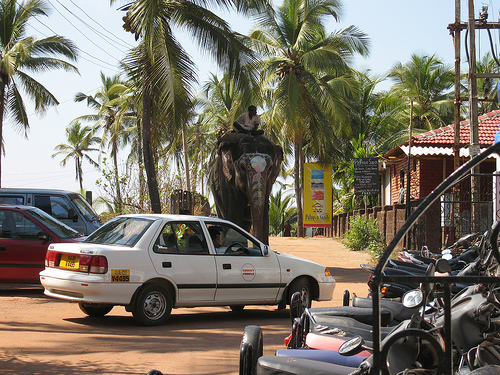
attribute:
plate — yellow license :
[55, 256, 82, 273]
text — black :
[63, 259, 77, 269]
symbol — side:
[238, 257, 260, 283]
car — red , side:
[3, 200, 83, 320]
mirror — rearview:
[399, 286, 434, 319]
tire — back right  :
[133, 281, 178, 328]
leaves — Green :
[311, 77, 353, 113]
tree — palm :
[118, 42, 209, 199]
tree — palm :
[106, 18, 272, 207]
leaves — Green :
[223, 55, 257, 95]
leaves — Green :
[324, 92, 352, 112]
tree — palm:
[249, 70, 369, 161]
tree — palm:
[266, 14, 376, 161]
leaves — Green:
[329, 75, 360, 113]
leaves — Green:
[294, 73, 346, 111]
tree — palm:
[239, 4, 374, 165]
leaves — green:
[94, 79, 132, 126]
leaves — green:
[71, 124, 96, 156]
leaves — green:
[67, 129, 92, 147]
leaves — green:
[415, 76, 437, 105]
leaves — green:
[411, 64, 446, 87]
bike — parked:
[366, 229, 498, 373]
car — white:
[34, 208, 346, 319]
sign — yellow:
[299, 158, 337, 229]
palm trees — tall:
[5, 1, 475, 245]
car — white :
[48, 211, 340, 324]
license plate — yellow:
[53, 254, 83, 274]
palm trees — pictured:
[73, 80, 496, 223]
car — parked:
[6, 200, 96, 297]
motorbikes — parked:
[218, 228, 498, 371]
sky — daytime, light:
[2, 0, 498, 226]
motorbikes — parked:
[225, 216, 496, 371]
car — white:
[22, 187, 358, 327]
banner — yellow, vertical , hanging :
[273, 124, 356, 244]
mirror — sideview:
[329, 330, 369, 360]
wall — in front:
[337, 134, 440, 251]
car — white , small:
[24, 205, 346, 333]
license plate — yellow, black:
[44, 253, 92, 275]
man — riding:
[219, 97, 295, 147]